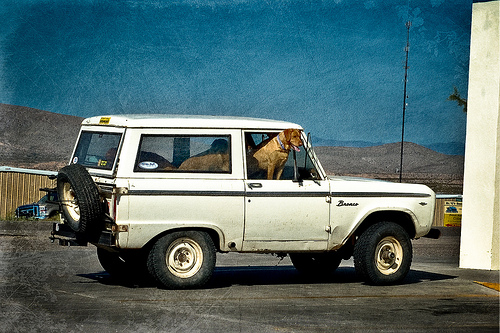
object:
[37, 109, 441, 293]
jeep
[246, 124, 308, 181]
dog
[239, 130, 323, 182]
window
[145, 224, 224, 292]
tire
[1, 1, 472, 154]
sky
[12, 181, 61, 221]
truck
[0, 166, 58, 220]
fence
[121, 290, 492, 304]
line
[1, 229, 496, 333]
pavement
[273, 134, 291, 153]
collar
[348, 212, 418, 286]
tire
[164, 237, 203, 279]
hubcap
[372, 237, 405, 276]
hubcap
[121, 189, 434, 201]
stripe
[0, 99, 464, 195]
mountain range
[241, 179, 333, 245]
door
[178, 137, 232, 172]
dogs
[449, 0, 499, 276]
building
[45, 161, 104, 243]
tire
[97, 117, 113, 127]
sticker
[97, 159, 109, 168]
sticker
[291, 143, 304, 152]
mouth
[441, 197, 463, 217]
sign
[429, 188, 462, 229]
building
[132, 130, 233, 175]
window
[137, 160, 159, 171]
sticker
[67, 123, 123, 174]
window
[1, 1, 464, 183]
horizon